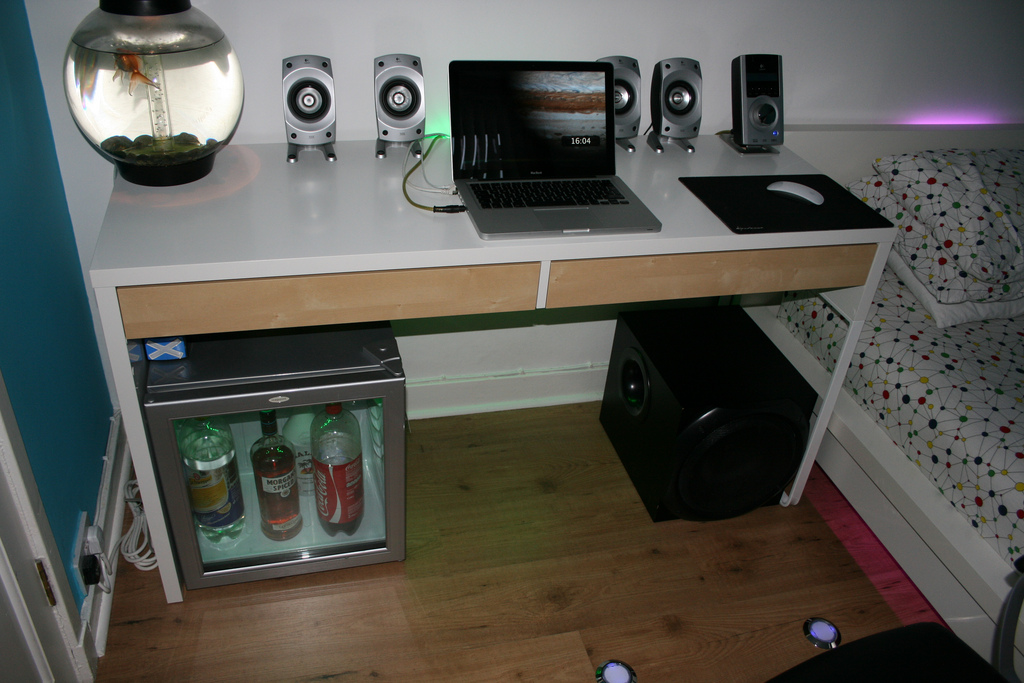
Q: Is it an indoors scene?
A: Yes, it is indoors.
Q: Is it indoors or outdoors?
A: It is indoors.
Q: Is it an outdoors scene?
A: No, it is indoors.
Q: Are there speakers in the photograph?
A: Yes, there are speakers.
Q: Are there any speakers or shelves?
A: Yes, there are speakers.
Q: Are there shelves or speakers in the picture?
A: Yes, there are speakers.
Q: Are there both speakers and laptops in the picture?
A: Yes, there are both speakers and a laptop.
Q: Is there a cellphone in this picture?
A: No, there are no cell phones.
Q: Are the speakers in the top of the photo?
A: Yes, the speakers are in the top of the image.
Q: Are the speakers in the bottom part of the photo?
A: No, the speakers are in the top of the image.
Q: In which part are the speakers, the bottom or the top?
A: The speakers are in the top of the image.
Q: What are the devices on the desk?
A: The devices are speakers.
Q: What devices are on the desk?
A: The devices are speakers.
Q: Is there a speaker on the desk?
A: Yes, there are speakers on the desk.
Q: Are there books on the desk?
A: No, there are speakers on the desk.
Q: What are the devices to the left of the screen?
A: The devices are speakers.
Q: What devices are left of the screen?
A: The devices are speakers.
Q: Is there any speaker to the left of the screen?
A: Yes, there are speakers to the left of the screen.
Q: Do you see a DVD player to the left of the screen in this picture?
A: No, there are speakers to the left of the screen.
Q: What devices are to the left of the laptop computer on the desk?
A: The devices are speakers.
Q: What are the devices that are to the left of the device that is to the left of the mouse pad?
A: The devices are speakers.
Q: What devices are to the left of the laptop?
A: The devices are speakers.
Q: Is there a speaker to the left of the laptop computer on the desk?
A: Yes, there are speakers to the left of the laptop.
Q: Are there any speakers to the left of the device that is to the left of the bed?
A: Yes, there are speakers to the left of the laptop.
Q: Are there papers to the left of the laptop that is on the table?
A: No, there are speakers to the left of the laptop computer.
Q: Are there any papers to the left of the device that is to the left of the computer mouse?
A: No, there are speakers to the left of the laptop computer.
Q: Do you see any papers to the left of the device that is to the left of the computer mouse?
A: No, there are speakers to the left of the laptop computer.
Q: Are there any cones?
A: No, there are no cones.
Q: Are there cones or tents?
A: No, there are no cones or tents.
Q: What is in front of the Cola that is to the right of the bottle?
A: The glass is in front of the Coke.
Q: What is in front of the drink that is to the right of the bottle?
A: The glass is in front of the Coke.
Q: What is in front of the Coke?
A: The glass is in front of the Coke.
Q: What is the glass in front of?
A: The glass is in front of the coca-cola.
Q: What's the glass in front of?
A: The glass is in front of the coca-cola.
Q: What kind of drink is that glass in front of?
A: The glass is in front of the Coke.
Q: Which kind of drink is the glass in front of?
A: The glass is in front of the Coke.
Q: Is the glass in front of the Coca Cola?
A: Yes, the glass is in front of the Coca Cola.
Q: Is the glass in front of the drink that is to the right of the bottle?
A: Yes, the glass is in front of the Coca Cola.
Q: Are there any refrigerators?
A: Yes, there is a refrigerator.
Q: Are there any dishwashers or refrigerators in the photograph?
A: Yes, there is a refrigerator.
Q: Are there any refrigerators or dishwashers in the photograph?
A: Yes, there is a refrigerator.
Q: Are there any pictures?
A: No, there are no pictures.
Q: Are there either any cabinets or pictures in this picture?
A: No, there are no pictures or cabinets.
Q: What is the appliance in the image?
A: The appliance is a refrigerator.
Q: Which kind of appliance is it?
A: The appliance is a refrigerator.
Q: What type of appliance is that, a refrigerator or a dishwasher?
A: That is a refrigerator.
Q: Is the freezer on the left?
A: Yes, the freezer is on the left of the image.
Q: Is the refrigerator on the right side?
A: No, the refrigerator is on the left of the image.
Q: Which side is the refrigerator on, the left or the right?
A: The refrigerator is on the left of the image.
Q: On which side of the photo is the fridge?
A: The fridge is on the left of the image.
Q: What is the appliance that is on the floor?
A: The appliance is a refrigerator.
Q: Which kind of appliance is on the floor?
A: The appliance is a refrigerator.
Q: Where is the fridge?
A: The fridge is on the floor.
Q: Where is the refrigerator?
A: The fridge is on the floor.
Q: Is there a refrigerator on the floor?
A: Yes, there is a refrigerator on the floor.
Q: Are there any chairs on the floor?
A: No, there is a refrigerator on the floor.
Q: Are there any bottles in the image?
A: Yes, there is a bottle.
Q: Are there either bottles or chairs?
A: Yes, there is a bottle.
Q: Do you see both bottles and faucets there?
A: No, there is a bottle but no faucets.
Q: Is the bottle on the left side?
A: Yes, the bottle is on the left of the image.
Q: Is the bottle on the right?
A: No, the bottle is on the left of the image.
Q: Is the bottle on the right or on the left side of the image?
A: The bottle is on the left of the image.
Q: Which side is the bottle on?
A: The bottle is on the left of the image.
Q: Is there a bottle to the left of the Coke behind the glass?
A: Yes, there is a bottle to the left of the Coke.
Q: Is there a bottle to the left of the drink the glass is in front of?
A: Yes, there is a bottle to the left of the Coke.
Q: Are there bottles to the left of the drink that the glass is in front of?
A: Yes, there is a bottle to the left of the Coke.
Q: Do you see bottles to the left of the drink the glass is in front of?
A: Yes, there is a bottle to the left of the Coke.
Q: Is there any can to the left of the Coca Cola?
A: No, there is a bottle to the left of the Coca Cola.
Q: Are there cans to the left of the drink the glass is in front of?
A: No, there is a bottle to the left of the Coca Cola.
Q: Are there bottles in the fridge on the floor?
A: Yes, there is a bottle in the fridge.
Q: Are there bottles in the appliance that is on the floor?
A: Yes, there is a bottle in the fridge.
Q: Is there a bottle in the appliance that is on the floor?
A: Yes, there is a bottle in the fridge.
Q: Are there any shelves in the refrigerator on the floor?
A: No, there is a bottle in the fridge.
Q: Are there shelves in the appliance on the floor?
A: No, there is a bottle in the fridge.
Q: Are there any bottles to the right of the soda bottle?
A: Yes, there is a bottle to the right of the soda bottle.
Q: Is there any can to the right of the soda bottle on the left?
A: No, there is a bottle to the right of the soda bottle.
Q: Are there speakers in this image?
A: Yes, there is a speaker.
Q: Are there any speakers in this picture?
A: Yes, there is a speaker.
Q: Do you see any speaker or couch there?
A: Yes, there is a speaker.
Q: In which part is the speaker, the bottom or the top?
A: The speaker is in the top of the image.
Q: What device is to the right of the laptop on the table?
A: The device is a speaker.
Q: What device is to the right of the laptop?
A: The device is a speaker.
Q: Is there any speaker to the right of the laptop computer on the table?
A: Yes, there is a speaker to the right of the laptop.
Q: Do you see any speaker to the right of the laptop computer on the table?
A: Yes, there is a speaker to the right of the laptop.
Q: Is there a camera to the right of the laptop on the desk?
A: No, there is a speaker to the right of the laptop.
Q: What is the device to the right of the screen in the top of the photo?
A: The device is a speaker.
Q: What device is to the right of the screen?
A: The device is a speaker.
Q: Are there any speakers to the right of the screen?
A: Yes, there is a speaker to the right of the screen.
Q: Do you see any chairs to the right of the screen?
A: No, there is a speaker to the right of the screen.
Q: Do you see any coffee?
A: No, there is no coffee.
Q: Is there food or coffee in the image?
A: No, there are no coffee or food.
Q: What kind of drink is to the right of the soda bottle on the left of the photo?
A: The drink is Coke.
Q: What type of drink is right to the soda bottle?
A: The drink is Coke.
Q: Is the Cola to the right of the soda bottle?
A: Yes, the Cola is to the right of the soda bottle.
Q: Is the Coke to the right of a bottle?
A: Yes, the Coke is to the right of a bottle.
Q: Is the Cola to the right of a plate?
A: No, the Cola is to the right of a bottle.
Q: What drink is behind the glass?
A: The drink is Coke.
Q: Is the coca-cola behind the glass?
A: Yes, the coca-cola is behind the glass.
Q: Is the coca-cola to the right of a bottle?
A: Yes, the coca-cola is to the right of a bottle.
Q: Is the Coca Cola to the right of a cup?
A: No, the Coca Cola is to the right of a bottle.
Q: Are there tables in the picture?
A: Yes, there is a table.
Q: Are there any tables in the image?
A: Yes, there is a table.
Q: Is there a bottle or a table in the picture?
A: Yes, there is a table.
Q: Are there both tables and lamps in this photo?
A: No, there is a table but no lamps.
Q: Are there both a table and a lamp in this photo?
A: No, there is a table but no lamps.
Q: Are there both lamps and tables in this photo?
A: No, there is a table but no lamps.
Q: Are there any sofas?
A: No, there are no sofas.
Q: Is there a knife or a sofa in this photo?
A: No, there are no sofas or knives.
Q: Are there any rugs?
A: No, there are no rugs.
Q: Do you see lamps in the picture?
A: No, there are no lamps.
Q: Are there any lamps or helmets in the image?
A: No, there are no lamps or helmets.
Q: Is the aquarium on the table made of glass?
A: Yes, the aquarium is made of glass.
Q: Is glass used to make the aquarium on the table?
A: Yes, the aquarium is made of glass.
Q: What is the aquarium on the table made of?
A: The aquarium is made of glass.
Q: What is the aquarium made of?
A: The aquarium is made of glass.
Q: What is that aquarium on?
A: The aquarium is on the table.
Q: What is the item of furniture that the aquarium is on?
A: The piece of furniture is a table.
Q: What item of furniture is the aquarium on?
A: The aquarium is on the table.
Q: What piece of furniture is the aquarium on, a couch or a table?
A: The aquarium is on a table.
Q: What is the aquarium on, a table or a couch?
A: The aquarium is on a table.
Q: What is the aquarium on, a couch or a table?
A: The aquarium is on a table.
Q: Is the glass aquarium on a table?
A: Yes, the aquarium is on a table.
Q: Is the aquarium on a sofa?
A: No, the aquarium is on a table.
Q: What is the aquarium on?
A: The aquarium is on the table.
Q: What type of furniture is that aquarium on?
A: The aquarium is on the table.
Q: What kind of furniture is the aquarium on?
A: The aquarium is on the table.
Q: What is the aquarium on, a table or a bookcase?
A: The aquarium is on a table.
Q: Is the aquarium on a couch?
A: No, the aquarium is on the table.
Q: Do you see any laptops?
A: Yes, there is a laptop.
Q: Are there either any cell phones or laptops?
A: Yes, there is a laptop.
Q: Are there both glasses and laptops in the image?
A: Yes, there are both a laptop and glasses.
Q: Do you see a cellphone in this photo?
A: No, there are no cell phones.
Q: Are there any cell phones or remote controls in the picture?
A: No, there are no cell phones or remote controls.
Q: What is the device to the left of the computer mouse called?
A: The device is a laptop.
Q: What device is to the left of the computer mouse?
A: The device is a laptop.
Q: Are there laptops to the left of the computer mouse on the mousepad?
A: Yes, there is a laptop to the left of the computer mouse.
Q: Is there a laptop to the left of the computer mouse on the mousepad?
A: Yes, there is a laptop to the left of the computer mouse.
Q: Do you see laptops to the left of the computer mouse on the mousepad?
A: Yes, there is a laptop to the left of the computer mouse.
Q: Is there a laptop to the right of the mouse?
A: No, the laptop is to the left of the mouse.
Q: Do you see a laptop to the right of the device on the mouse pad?
A: No, the laptop is to the left of the mouse.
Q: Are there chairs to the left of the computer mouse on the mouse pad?
A: No, there is a laptop to the left of the mouse.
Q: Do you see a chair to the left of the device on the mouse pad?
A: No, there is a laptop to the left of the mouse.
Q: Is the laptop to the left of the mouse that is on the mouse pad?
A: Yes, the laptop is to the left of the mouse.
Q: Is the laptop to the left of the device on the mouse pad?
A: Yes, the laptop is to the left of the mouse.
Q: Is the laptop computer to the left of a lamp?
A: No, the laptop computer is to the left of the mouse.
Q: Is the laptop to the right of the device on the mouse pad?
A: No, the laptop is to the left of the mouse.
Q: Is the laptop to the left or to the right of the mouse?
A: The laptop is to the left of the mouse.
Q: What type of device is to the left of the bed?
A: The device is a laptop.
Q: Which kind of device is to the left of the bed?
A: The device is a laptop.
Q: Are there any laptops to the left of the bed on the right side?
A: Yes, there is a laptop to the left of the bed.